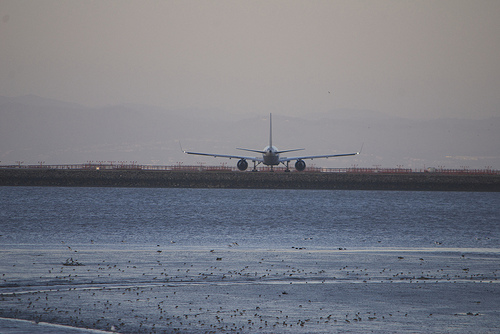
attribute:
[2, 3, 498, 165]
grey sky — foggy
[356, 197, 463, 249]
water — mass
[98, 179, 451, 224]
water — mass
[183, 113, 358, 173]
airplane — flying, low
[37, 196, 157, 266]
water — mass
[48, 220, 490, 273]
water — mass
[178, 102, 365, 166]
plane — tail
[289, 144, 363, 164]
wing — rear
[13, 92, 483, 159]
mountains — high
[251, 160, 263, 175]
wheels — deployed, back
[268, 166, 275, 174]
wheels — deployed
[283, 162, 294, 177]
wheels — deployed, back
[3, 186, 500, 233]
water — blue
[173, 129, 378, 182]
airplane — flying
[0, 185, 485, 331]
water — mass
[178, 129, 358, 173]
plane — big